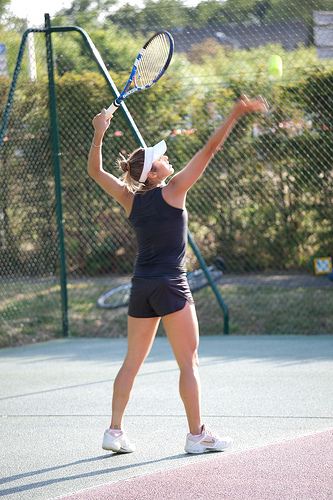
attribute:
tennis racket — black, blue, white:
[100, 25, 172, 116]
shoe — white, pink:
[187, 423, 234, 451]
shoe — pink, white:
[98, 423, 136, 457]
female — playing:
[85, 100, 272, 460]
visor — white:
[136, 143, 170, 185]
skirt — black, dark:
[126, 270, 188, 319]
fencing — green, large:
[4, 2, 331, 335]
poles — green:
[3, 9, 233, 335]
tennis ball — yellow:
[266, 54, 287, 81]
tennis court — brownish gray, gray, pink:
[5, 332, 331, 499]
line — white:
[43, 412, 331, 493]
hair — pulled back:
[119, 144, 159, 190]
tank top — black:
[125, 192, 190, 272]